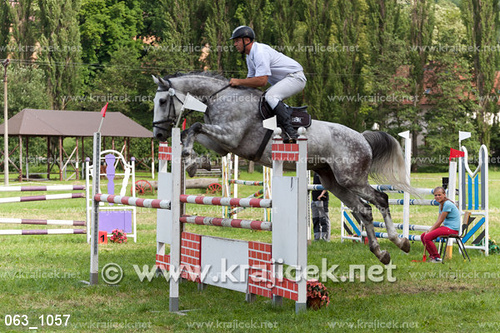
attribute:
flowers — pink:
[308, 282, 330, 311]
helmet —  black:
[226, 22, 268, 44]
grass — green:
[1, 162, 498, 324]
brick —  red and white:
[120, 225, 338, 309]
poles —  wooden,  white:
[150, 128, 485, 309]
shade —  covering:
[0, 107, 161, 138]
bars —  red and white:
[93, 190, 168, 212]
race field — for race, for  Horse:
[1, 73, 497, 331]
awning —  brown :
[0, 102, 146, 174]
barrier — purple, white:
[0, 170, 103, 249]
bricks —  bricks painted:
[136, 217, 322, 306]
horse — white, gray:
[160, 81, 440, 265]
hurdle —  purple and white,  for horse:
[0, 185, 88, 237]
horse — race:
[183, 61, 368, 199]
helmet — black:
[228, 22, 257, 44]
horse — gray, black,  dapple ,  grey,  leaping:
[144, 67, 411, 264]